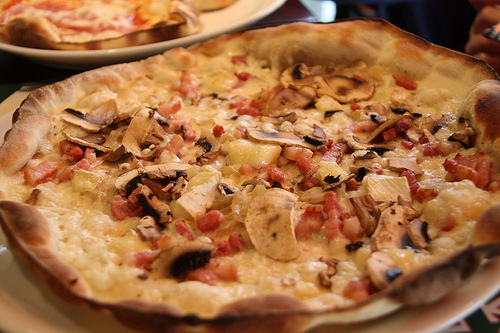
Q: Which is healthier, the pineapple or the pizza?
A: The pineapple is healthier than the pizza.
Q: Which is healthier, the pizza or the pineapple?
A: The pineapple is healthier than the pizza.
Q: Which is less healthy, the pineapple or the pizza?
A: The pizza is less healthy than the pineapple.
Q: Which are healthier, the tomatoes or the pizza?
A: The tomatoes are healthier than the pizza.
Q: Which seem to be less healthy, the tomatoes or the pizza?
A: The pizza are less healthy than the tomatoes.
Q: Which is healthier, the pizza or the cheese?
A: The cheese is healthier than the pizza.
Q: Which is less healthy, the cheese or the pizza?
A: The pizza is less healthy than the cheese.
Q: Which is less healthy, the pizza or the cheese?
A: The pizza is less healthy than the cheese.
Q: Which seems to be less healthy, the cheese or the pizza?
A: The pizza is less healthy than the cheese.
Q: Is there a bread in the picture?
A: Yes, there is a bread.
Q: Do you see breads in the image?
A: Yes, there is a bread.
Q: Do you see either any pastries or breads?
A: Yes, there is a bread.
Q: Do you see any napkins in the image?
A: No, there are no napkins.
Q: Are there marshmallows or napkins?
A: No, there are no napkins or marshmallows.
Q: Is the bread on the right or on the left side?
A: The bread is on the left of the image.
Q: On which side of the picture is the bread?
A: The bread is on the left of the image.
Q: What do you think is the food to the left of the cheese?
A: The food is a bread.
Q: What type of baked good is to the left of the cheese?
A: The food is a bread.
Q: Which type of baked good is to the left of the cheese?
A: The food is a bread.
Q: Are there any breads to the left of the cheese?
A: Yes, there is a bread to the left of the cheese.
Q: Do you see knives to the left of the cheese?
A: No, there is a bread to the left of the cheese.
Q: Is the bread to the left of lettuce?
A: No, the bread is to the left of the cheese.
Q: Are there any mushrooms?
A: Yes, there are mushrooms.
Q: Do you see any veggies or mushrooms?
A: Yes, there are mushrooms.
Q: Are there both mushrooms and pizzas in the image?
A: Yes, there are both mushrooms and a pizza.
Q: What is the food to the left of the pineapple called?
A: The food is mushrooms.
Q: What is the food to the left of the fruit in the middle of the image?
A: The food is mushrooms.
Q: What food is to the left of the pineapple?
A: The food is mushrooms.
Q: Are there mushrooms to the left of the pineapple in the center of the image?
A: Yes, there are mushrooms to the left of the pineapple.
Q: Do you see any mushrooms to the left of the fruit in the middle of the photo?
A: Yes, there are mushrooms to the left of the pineapple.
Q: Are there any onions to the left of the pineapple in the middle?
A: No, there are mushrooms to the left of the pineapple.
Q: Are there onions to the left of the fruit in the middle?
A: No, there are mushrooms to the left of the pineapple.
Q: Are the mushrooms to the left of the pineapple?
A: Yes, the mushrooms are to the left of the pineapple.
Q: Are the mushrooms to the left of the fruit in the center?
A: Yes, the mushrooms are to the left of the pineapple.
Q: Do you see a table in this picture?
A: Yes, there is a table.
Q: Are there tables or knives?
A: Yes, there is a table.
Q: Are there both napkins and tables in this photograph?
A: No, there is a table but no napkins.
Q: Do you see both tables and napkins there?
A: No, there is a table but no napkins.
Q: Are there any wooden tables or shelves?
A: Yes, there is a wood table.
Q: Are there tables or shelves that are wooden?
A: Yes, the table is wooden.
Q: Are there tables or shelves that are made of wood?
A: Yes, the table is made of wood.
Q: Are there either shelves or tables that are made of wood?
A: Yes, the table is made of wood.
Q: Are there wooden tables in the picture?
A: Yes, there is a wood table.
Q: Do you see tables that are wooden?
A: Yes, there is a table that is wooden.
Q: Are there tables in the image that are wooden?
A: Yes, there is a table that is wooden.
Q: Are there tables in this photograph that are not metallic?
A: Yes, there is a wooden table.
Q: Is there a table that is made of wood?
A: Yes, there is a table that is made of wood.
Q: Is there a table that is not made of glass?
A: Yes, there is a table that is made of wood.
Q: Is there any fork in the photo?
A: No, there are no forks.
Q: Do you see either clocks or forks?
A: No, there are no forks or clocks.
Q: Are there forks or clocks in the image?
A: No, there are no forks or clocks.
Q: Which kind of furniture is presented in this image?
A: The furniture is a table.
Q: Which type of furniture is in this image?
A: The furniture is a table.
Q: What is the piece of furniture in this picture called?
A: The piece of furniture is a table.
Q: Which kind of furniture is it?
A: The piece of furniture is a table.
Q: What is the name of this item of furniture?
A: This is a table.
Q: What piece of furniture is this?
A: This is a table.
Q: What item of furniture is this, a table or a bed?
A: This is a table.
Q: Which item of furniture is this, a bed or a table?
A: This is a table.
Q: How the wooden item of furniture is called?
A: The piece of furniture is a table.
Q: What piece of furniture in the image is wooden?
A: The piece of furniture is a table.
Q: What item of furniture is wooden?
A: The piece of furniture is a table.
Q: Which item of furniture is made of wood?
A: The piece of furniture is a table.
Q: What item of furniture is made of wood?
A: The piece of furniture is a table.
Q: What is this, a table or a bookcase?
A: This is a table.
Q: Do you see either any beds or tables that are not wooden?
A: No, there is a table but it is wooden.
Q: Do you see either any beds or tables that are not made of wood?
A: No, there is a table but it is made of wood.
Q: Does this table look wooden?
A: Yes, the table is wooden.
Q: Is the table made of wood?
A: Yes, the table is made of wood.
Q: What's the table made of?
A: The table is made of wood.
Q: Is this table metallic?
A: No, the table is wooden.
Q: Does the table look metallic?
A: No, the table is wooden.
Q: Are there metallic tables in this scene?
A: No, there is a table but it is wooden.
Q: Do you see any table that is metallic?
A: No, there is a table but it is wooden.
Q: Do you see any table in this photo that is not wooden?
A: No, there is a table but it is wooden.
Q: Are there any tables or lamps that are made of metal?
A: No, there is a table but it is made of wood.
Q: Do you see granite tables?
A: No, there is a table but it is made of wood.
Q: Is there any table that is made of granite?
A: No, there is a table but it is made of wood.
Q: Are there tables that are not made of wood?
A: No, there is a table but it is made of wood.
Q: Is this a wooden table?
A: Yes, this is a wooden table.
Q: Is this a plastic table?
A: No, this is a wooden table.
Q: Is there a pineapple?
A: Yes, there is a pineapple.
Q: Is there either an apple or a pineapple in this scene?
A: Yes, there is a pineapple.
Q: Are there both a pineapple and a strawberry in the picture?
A: No, there is a pineapple but no strawberries.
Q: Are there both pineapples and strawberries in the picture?
A: No, there is a pineapple but no strawberries.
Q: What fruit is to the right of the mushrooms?
A: The fruit is a pineapple.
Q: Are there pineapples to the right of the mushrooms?
A: Yes, there is a pineapple to the right of the mushrooms.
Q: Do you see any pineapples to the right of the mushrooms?
A: Yes, there is a pineapple to the right of the mushrooms.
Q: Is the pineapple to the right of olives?
A: No, the pineapple is to the right of the mushrooms.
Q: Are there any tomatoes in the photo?
A: Yes, there are tomatoes.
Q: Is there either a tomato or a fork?
A: Yes, there are tomatoes.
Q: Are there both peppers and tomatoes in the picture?
A: No, there are tomatoes but no peppers.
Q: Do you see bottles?
A: No, there are no bottles.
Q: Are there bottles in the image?
A: No, there are no bottles.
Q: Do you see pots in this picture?
A: No, there are no pots.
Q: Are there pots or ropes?
A: No, there are no pots or ropes.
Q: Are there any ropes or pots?
A: No, there are no pots or ropes.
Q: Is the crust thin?
A: Yes, the crust is thin.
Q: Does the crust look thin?
A: Yes, the crust is thin.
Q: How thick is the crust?
A: The crust is thin.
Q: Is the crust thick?
A: No, the crust is thin.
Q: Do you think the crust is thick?
A: No, the crust is thin.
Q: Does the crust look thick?
A: No, the crust is thin.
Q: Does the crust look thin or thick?
A: The crust is thin.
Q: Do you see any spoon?
A: No, there are no spoons.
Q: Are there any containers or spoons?
A: No, there are no spoons or containers.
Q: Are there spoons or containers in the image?
A: No, there are no spoons or containers.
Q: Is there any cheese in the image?
A: Yes, there is cheese.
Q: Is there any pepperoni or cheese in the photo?
A: Yes, there is cheese.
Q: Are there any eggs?
A: No, there are no eggs.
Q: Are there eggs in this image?
A: No, there are no eggs.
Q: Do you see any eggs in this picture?
A: No, there are no eggs.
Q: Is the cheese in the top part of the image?
A: Yes, the cheese is in the top of the image.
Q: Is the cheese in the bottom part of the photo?
A: No, the cheese is in the top of the image.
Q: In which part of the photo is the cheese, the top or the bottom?
A: The cheese is in the top of the image.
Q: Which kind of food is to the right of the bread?
A: The food is cheese.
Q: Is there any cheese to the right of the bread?
A: Yes, there is cheese to the right of the bread.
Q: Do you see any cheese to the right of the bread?
A: Yes, there is cheese to the right of the bread.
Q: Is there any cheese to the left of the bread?
A: No, the cheese is to the right of the bread.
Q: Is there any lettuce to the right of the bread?
A: No, there is cheese to the right of the bread.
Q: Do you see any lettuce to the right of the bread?
A: No, there is cheese to the right of the bread.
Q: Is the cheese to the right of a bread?
A: Yes, the cheese is to the right of a bread.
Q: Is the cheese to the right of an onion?
A: No, the cheese is to the right of a bread.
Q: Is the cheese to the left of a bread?
A: No, the cheese is to the right of a bread.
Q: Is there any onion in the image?
A: No, there are no onions.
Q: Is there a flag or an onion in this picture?
A: No, there are no onions or flags.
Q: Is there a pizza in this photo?
A: Yes, there is a pizza.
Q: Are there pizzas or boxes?
A: Yes, there is a pizza.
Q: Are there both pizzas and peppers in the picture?
A: No, there is a pizza but no peppers.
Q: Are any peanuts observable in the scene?
A: No, there are no peanuts.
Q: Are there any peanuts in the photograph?
A: No, there are no peanuts.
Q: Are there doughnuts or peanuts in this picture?
A: No, there are no peanuts or doughnuts.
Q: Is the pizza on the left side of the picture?
A: Yes, the pizza is on the left of the image.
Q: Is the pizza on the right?
A: No, the pizza is on the left of the image.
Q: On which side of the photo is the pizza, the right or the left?
A: The pizza is on the left of the image.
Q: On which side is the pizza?
A: The pizza is on the left of the image.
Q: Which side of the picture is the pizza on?
A: The pizza is on the left of the image.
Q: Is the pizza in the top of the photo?
A: Yes, the pizza is in the top of the image.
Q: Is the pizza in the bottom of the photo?
A: No, the pizza is in the top of the image.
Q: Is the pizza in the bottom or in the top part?
A: The pizza is in the top of the image.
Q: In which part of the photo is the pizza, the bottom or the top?
A: The pizza is in the top of the image.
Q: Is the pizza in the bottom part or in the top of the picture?
A: The pizza is in the top of the image.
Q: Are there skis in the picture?
A: No, there are no skis.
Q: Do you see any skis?
A: No, there are no skis.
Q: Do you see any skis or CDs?
A: No, there are no skis or cds.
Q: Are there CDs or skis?
A: No, there are no skis or cds.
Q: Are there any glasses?
A: No, there are no glasses.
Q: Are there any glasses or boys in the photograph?
A: No, there are no glasses or boys.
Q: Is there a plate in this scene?
A: Yes, there is a plate.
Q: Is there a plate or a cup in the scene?
A: Yes, there is a plate.